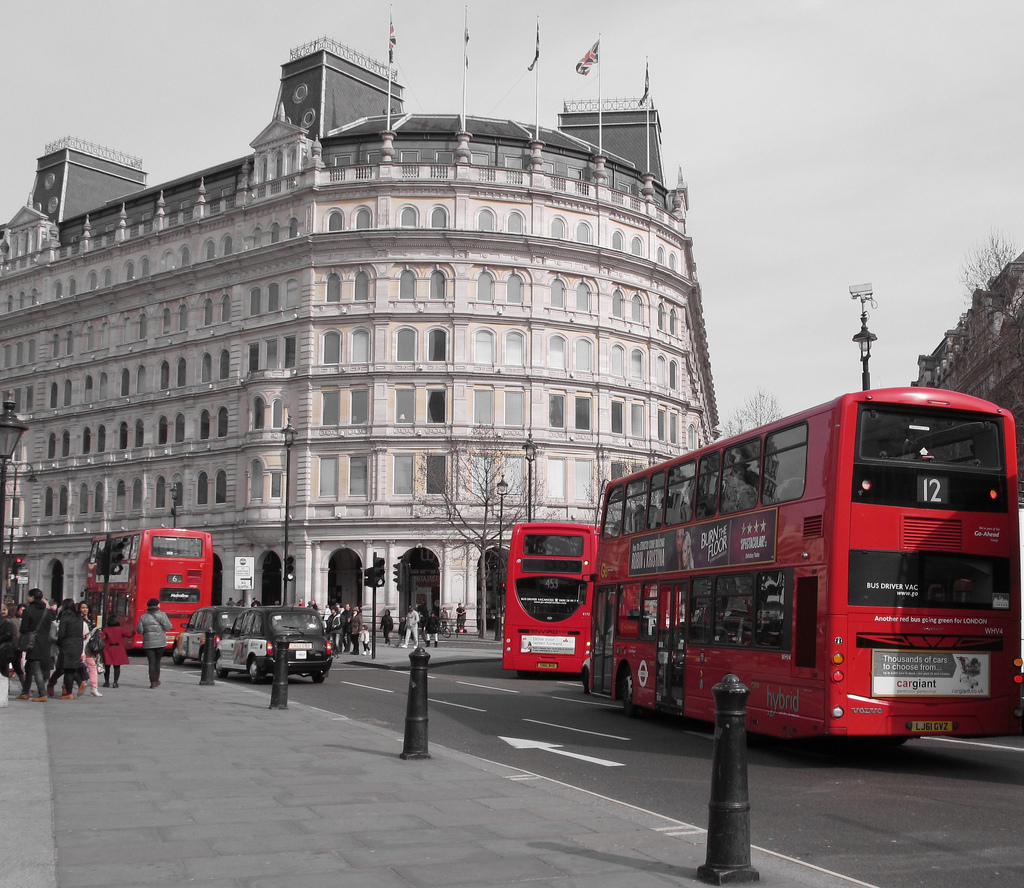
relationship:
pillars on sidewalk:
[399, 648, 432, 761] [94, 683, 516, 858]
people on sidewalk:
[41, 586, 232, 686] [49, 705, 453, 881]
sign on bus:
[844, 627, 1007, 703] [578, 409, 1019, 831]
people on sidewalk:
[135, 598, 171, 688] [38, 677, 358, 859]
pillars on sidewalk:
[181, 616, 491, 764] [64, 653, 458, 876]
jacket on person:
[120, 608, 187, 652] [125, 592, 232, 714]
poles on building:
[315, 29, 665, 140] [32, 124, 826, 716]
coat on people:
[77, 625, 132, 675] [135, 598, 171, 688]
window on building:
[382, 303, 480, 384] [155, 169, 761, 647]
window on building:
[418, 379, 455, 436] [1, 16, 719, 639]